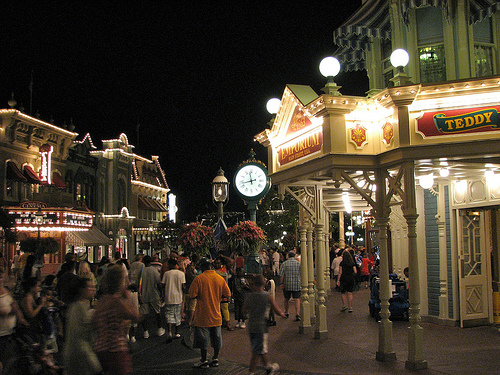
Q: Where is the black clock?
A: Outside the building.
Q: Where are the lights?
A: On top of the building.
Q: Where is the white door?
A: On a building.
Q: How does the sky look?
A: Dark.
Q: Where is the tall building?
A: To the left.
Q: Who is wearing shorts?
A: A boy.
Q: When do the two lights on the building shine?
A: At nightime.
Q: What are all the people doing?
A: Walking down the street.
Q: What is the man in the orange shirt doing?
A: Standing there.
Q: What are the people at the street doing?
A: Shopping.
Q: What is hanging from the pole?
A: Flowers.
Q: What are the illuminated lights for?
A: The store signs.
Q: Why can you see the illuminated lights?
A: It's nighttime.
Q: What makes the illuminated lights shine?
A: Electricity.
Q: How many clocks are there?
A: One.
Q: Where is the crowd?
A: In the street.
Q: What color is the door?
A: White.